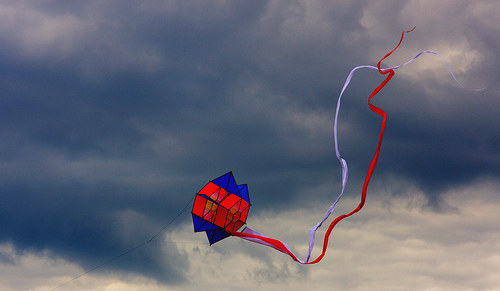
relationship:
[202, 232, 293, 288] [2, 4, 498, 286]
string blends with sky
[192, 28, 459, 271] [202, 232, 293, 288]
kite has a string